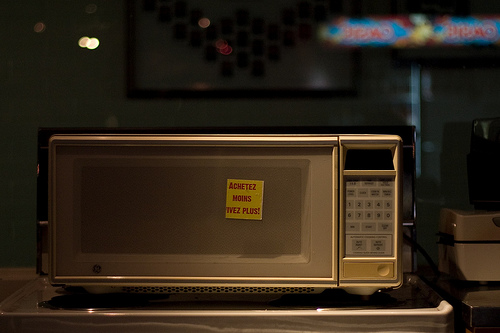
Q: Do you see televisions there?
A: No, there are no televisions.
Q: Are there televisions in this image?
A: No, there are no televisions.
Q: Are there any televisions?
A: No, there are no televisions.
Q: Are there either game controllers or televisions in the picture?
A: No, there are no televisions or game controllers.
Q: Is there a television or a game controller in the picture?
A: No, there are no televisions or game controllers.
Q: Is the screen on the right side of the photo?
A: Yes, the screen is on the right of the image.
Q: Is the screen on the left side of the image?
A: No, the screen is on the right of the image.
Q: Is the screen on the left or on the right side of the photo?
A: The screen is on the right of the image.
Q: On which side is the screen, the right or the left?
A: The screen is on the right of the image.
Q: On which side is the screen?
A: The screen is on the right of the image.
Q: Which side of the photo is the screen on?
A: The screen is on the right of the image.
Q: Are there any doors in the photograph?
A: Yes, there is a door.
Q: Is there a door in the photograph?
A: Yes, there is a door.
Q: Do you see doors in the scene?
A: Yes, there is a door.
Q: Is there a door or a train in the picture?
A: Yes, there is a door.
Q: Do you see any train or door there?
A: Yes, there is a door.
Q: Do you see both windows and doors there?
A: No, there is a door but no windows.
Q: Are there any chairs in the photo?
A: No, there are no chairs.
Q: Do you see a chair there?
A: No, there are no chairs.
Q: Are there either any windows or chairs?
A: No, there are no chairs or windows.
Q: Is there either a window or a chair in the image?
A: No, there are no chairs or windows.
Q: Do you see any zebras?
A: Yes, there is a zebra.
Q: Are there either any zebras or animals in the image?
A: Yes, there is a zebra.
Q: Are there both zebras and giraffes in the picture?
A: No, there is a zebra but no giraffes.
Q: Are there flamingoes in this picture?
A: No, there are no flamingoes.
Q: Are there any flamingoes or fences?
A: No, there are no flamingoes or fences.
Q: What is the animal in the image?
A: The animal is a zebra.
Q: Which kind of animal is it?
A: The animal is a zebra.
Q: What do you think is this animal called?
A: This is a zebra.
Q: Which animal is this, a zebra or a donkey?
A: This is a zebra.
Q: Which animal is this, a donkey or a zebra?
A: This is a zebra.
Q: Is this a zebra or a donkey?
A: This is a zebra.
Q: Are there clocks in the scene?
A: No, there are no clocks.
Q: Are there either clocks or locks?
A: No, there are no clocks or locks.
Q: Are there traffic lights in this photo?
A: No, there are no traffic lights.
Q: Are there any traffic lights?
A: No, there are no traffic lights.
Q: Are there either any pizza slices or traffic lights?
A: No, there are no traffic lights or pizza slices.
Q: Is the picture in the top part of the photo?
A: Yes, the picture is in the top of the image.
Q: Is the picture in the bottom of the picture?
A: No, the picture is in the top of the image.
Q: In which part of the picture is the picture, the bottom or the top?
A: The picture is in the top of the image.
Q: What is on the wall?
A: The picture is on the wall.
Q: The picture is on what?
A: The picture is on the wall.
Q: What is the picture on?
A: The picture is on the wall.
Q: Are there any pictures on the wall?
A: Yes, there is a picture on the wall.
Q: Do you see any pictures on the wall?
A: Yes, there is a picture on the wall.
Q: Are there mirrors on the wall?
A: No, there is a picture on the wall.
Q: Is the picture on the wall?
A: Yes, the picture is on the wall.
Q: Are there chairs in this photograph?
A: No, there are no chairs.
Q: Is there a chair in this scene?
A: No, there are no chairs.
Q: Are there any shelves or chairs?
A: No, there are no chairs or shelves.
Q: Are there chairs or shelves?
A: No, there are no chairs or shelves.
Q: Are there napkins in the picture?
A: No, there are no napkins.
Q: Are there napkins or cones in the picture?
A: No, there are no napkins or cones.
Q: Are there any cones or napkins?
A: No, there are no napkins or cones.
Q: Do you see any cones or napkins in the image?
A: No, there are no napkins or cones.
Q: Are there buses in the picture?
A: No, there are no buses.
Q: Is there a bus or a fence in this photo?
A: No, there are no buses or fences.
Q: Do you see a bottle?
A: No, there are no bottles.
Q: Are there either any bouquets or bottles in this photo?
A: No, there are no bottles or bouquets.